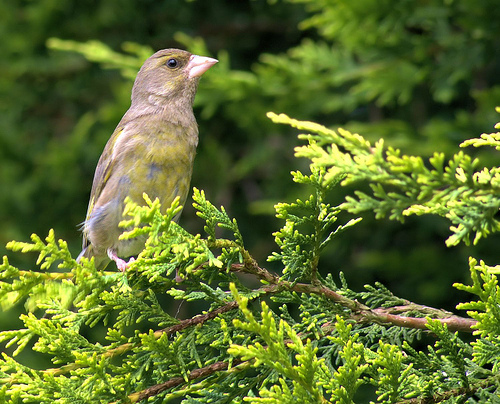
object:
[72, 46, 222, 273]
bird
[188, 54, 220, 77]
beak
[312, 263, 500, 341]
branch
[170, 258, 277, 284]
branch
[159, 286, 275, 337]
branch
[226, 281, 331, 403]
leaf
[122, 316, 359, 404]
branch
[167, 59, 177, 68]
eye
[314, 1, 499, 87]
leaves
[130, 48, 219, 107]
head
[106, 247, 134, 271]
foot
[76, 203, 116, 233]
feather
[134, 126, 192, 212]
stomach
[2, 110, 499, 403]
leaves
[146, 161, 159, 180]
spot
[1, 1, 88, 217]
tree